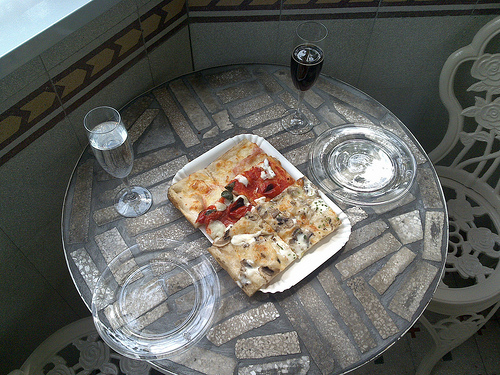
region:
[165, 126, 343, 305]
square sliced pizza on plate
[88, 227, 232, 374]
the plate is transparent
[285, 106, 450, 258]
the plate is transparent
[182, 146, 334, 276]
Various types of square pizzas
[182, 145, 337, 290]
Pizzas on white serving plate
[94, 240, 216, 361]
Clear glass dinner plate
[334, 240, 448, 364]
Round black table with inlaid stones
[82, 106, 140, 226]
Water in a tall glass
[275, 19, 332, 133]
Soda in large glass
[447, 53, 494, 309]
Outdoor chair with white flower design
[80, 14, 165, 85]
yellow and brown arrow border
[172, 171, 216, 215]
Piece of cheese pizza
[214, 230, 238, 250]
Piece of pizza with mushrooms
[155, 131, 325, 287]
square pizza on tray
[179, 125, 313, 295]
white tray on table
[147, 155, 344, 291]
white tray is rectangular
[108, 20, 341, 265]
two glasses on table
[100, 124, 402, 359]
two round plates on table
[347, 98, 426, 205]
round plates are clear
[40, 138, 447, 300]
table has grey stones inlaid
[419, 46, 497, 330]
grey chair next to table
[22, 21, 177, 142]
yellow arrows in wall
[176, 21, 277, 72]
grey stones in wall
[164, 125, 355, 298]
A pan full of food.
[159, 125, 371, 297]
a tray full of food.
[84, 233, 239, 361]
a glass plate on a table.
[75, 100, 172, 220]
A glass on a table.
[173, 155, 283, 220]
food on a container.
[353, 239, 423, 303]
A brick on the ground.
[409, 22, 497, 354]
A white chair near a table.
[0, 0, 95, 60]
A window sill.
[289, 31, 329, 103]
wine in a glass.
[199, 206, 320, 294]
food on a tray.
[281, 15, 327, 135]
glass of red wine is half full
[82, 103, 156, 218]
water is in a champagne glass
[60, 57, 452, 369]
table is made of stone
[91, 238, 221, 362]
round clear plate is empty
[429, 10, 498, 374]
white garden seat next to table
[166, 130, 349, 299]
white rectangular tray with pizza on it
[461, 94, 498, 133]
white rose on patio chair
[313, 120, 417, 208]
light is reflecting on the plate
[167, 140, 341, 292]
three different kinds of pizza on a tray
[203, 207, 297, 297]
piece of pizza is square